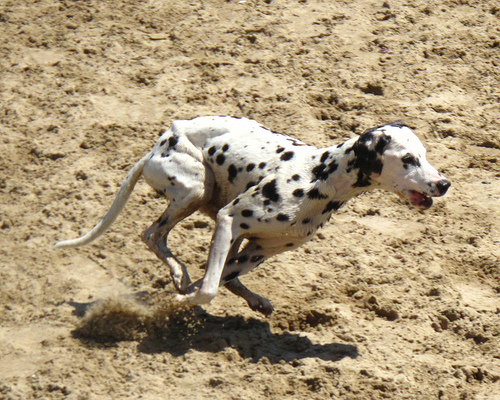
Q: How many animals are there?
A: One.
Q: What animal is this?
A: Dog.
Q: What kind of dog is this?
A: Dalmatian.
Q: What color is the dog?
A: Black and white.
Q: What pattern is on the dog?
A: Spots.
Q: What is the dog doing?
A: Running.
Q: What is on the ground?
A: Dirt.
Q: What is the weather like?
A: Sunny.